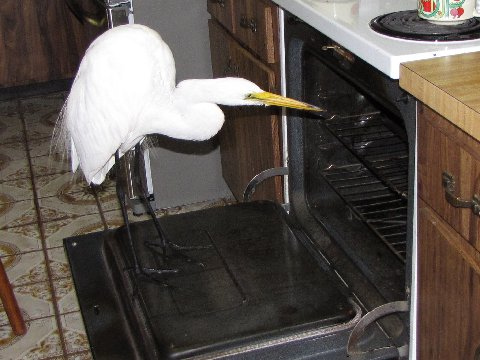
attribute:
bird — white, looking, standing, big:
[50, 24, 324, 299]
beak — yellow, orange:
[251, 91, 323, 112]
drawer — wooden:
[205, 0, 274, 60]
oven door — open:
[65, 196, 396, 357]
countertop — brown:
[401, 51, 480, 143]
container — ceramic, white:
[419, 0, 479, 28]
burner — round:
[370, 13, 480, 39]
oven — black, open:
[286, 19, 416, 351]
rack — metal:
[323, 109, 410, 203]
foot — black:
[144, 238, 210, 275]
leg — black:
[135, 142, 167, 244]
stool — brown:
[0, 257, 26, 336]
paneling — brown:
[2, 0, 111, 87]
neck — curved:
[170, 79, 225, 140]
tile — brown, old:
[38, 191, 100, 221]